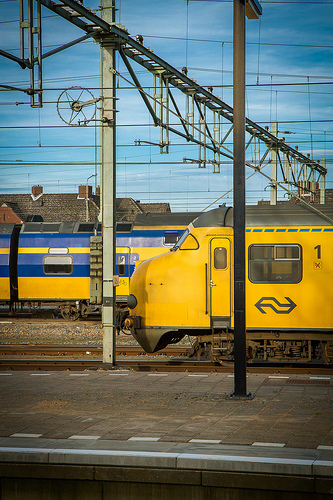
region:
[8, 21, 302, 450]
picture taken outdoors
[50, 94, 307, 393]
picture taken during the day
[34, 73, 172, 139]
white wispy clouds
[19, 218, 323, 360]
several trains on the tracks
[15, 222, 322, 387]
the trains are not moving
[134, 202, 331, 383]
the train is at a station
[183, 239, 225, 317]
the train is yellow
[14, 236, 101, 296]
the train is blue and yellow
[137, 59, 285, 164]
wires above the train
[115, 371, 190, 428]
bricks on the platform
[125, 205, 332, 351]
this is a train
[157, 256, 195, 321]
the train is yellow in color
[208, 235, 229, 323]
the door is closed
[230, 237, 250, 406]
this is a pole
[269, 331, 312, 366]
the wheels are metallic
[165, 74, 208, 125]
this is a bridge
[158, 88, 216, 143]
the metals are above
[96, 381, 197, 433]
this is the pavement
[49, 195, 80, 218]
this is the roof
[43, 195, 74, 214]
the roof is brown in color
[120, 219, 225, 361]
the train is yellow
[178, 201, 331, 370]
the train is yellow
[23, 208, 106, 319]
a yellow and blue train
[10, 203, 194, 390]
a yellow and blue train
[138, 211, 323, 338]
A yellow train on the track.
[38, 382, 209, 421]
Dirt on the sidewalk.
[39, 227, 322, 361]
Two trains on the tracks.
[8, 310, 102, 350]
Gravel between the tracks.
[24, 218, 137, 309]
The train is yellow and blue.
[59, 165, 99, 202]
The chimney on the roof.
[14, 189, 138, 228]
The roof of the house.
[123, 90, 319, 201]
Wires above the train.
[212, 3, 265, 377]
A pole with wires connected.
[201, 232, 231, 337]
A door on the train.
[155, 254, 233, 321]
the train is yellow in colour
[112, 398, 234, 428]
the floor is tiled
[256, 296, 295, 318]
the train has a diagram on it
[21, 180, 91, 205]
the house has chimneys on top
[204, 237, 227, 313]
the door is shut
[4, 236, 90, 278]
the train is blue and yellow in colour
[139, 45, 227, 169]
some metal frames are on the top of the train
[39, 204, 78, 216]
the roof is old and faded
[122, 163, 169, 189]
the sky is blue with some clouds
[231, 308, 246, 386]
the pole is mettalic